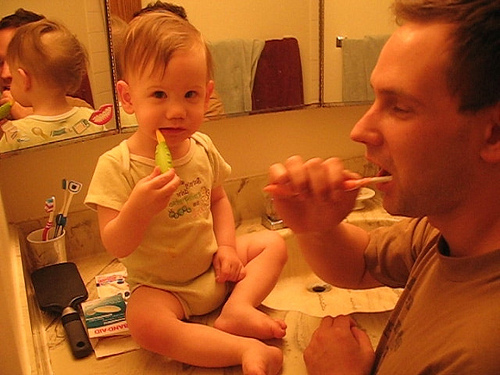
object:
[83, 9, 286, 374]
baby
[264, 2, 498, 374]
man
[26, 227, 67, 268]
cup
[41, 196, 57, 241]
toothbrush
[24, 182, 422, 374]
counter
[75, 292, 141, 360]
box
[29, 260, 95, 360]
brush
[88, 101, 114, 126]
sticker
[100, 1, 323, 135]
mirror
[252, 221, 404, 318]
sink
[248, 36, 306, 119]
towel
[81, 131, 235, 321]
onesie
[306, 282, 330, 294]
drain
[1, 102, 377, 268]
wall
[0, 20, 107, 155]
reflection